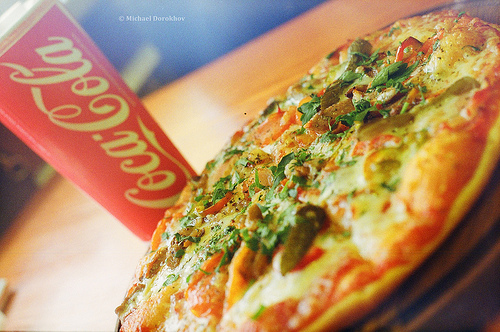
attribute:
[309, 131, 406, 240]
pizza — fully cooked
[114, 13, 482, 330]
pizza — person size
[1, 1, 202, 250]
cup — cardboard